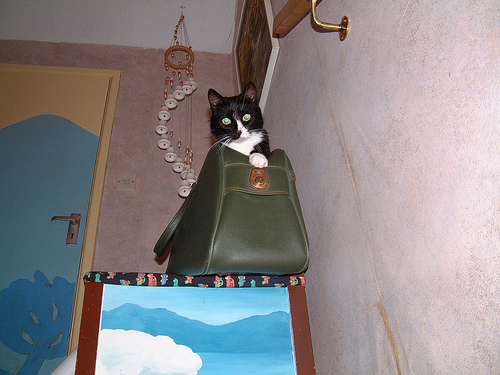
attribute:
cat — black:
[194, 65, 295, 159]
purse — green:
[145, 142, 307, 274]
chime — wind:
[151, 25, 214, 169]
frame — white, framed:
[215, 6, 286, 128]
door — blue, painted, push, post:
[90, 264, 297, 375]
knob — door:
[48, 179, 90, 250]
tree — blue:
[7, 274, 84, 359]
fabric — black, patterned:
[177, 175, 234, 240]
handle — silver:
[53, 207, 82, 241]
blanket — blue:
[105, 260, 285, 304]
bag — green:
[218, 175, 289, 231]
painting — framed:
[217, 20, 283, 91]